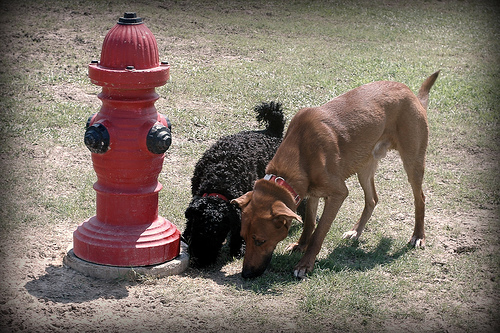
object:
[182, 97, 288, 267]
canine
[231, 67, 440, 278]
canine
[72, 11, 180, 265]
hydrant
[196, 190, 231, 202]
collar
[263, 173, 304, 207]
collar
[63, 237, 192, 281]
base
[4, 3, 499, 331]
earth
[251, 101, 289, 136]
tail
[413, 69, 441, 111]
tail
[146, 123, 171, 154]
knob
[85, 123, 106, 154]
knob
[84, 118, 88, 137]
knob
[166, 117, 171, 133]
knob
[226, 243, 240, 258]
paw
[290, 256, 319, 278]
paw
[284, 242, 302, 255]
paw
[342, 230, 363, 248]
paw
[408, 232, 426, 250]
paw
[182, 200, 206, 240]
ear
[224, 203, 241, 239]
ear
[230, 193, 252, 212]
ear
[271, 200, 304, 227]
ear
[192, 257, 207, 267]
nose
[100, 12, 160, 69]
top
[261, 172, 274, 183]
white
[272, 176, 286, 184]
silver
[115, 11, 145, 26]
valve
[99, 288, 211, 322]
dirt